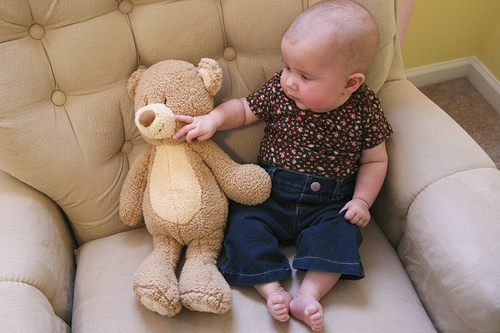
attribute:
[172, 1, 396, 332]
baby — pink, bald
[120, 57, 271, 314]
bear — brown, soft, tan, stuffed, floppy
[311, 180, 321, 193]
button — silver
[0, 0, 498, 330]
chair — tan, large, plush, buff, brown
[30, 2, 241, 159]
buttons — tan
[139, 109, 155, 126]
nose — brown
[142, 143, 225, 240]
tummy — pale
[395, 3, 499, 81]
wall — yellow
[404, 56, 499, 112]
baseboard — white